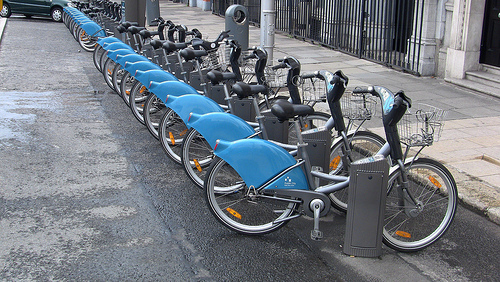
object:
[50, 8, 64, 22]
wheel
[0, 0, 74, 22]
car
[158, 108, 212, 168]
wheel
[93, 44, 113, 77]
wheel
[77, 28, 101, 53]
wheel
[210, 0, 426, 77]
fence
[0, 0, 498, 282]
sidewalk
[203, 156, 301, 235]
wheel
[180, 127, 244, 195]
wheel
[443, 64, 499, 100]
steps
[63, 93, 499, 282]
road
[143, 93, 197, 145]
wheel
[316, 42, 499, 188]
pavement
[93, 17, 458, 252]
bicycles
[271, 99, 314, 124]
seat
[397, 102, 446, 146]
basket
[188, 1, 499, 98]
building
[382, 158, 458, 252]
wheel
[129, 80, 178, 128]
wheel